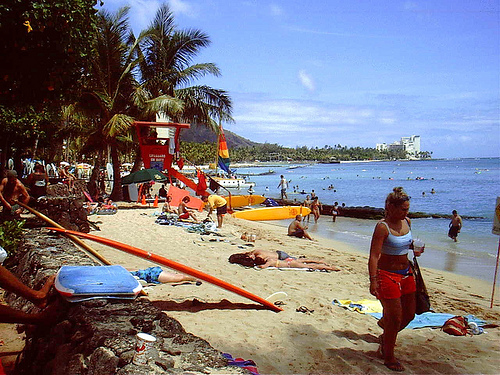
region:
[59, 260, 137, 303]
Blue surfboard on ground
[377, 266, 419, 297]
Orange shorts on woman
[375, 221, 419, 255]
White tank top on woman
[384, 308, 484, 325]
Light blue towel on sand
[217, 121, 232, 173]
Multicolored sail on boat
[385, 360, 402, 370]
Flip flop on woman's foot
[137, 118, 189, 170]
Red lifeguard tower on beach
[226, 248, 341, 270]
Sunbathers lying on sand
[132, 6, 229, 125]
Palm tree on beach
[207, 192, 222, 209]
Yellow shirt on person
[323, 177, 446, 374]
a woman walking on a beach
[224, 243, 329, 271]
two people laying on a beach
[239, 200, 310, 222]
a yellow surf board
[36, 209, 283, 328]
a orange surf board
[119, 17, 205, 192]
a tall palm tree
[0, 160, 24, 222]
a man without a shirt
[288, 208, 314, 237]
a man sitting on a beach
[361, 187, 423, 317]
a woman wearing red shorts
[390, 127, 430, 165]
a tall green building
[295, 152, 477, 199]
several people swimming in the ocean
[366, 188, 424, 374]
a woman walking on a beach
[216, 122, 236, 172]
a rainbow flag on a boat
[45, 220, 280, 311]
an orange surfboard propped on a stone ledge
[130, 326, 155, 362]
a plastic cup on a stone ledge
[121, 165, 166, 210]
a green umbrella on a beach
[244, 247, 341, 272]
two people sunbathing on the beach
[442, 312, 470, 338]
a red and white bag on the sand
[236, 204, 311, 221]
a yellow surfboard by the beach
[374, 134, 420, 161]
a white building by the ocean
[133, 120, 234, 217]
a life's guard red booth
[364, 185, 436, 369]
a woman walking on beach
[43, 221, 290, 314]
an orange and white surfboard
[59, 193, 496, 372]
a brown sandy beach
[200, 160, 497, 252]
a large body of water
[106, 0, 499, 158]
a cloudy blue sky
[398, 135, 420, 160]
a tall building in distance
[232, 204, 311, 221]
a long yellow surfboard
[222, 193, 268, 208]
a long yellow surfboard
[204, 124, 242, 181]
a rainbow colored sailboat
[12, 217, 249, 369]
a long dark rock wall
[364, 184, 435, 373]
a woman in orange shirts and a blue tank top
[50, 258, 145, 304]
paddle boards lying on the wall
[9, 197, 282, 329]
a pair of skis leaning against the wall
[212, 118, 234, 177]
a rainbow flag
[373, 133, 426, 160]
a white building in the background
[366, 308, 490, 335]
a blue towel in the sand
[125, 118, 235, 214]
a red lifeguard stand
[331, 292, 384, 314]
a yellow towel in the sand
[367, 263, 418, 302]
a pair of orange shorts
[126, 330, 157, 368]
a paper cup sitting on the wall